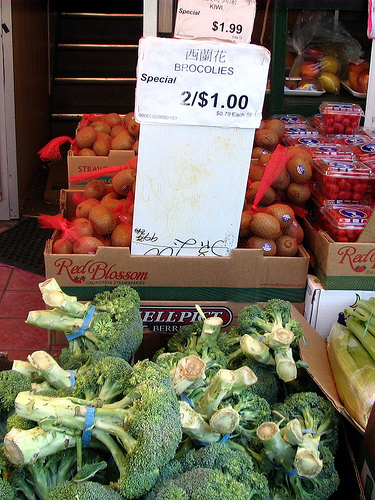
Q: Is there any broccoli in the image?
A: Yes, there is broccoli.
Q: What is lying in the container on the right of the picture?
A: The broccoli is lying in the box.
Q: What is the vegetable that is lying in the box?
A: The vegetable is broccoli.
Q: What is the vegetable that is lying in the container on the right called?
A: The vegetable is broccoli.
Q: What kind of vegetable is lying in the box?
A: The vegetable is broccoli.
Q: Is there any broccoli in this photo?
A: Yes, there is broccoli.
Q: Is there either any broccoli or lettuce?
A: Yes, there is broccoli.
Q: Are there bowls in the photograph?
A: No, there are no bowls.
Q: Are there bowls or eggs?
A: No, there are no bowls or eggs.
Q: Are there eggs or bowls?
A: No, there are no bowls or eggs.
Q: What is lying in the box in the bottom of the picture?
A: The broccoli is lying in the box.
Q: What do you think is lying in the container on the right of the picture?
A: The broccoli is lying in the box.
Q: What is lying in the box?
A: The broccoli is lying in the box.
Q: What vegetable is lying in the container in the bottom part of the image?
A: The vegetable is broccoli.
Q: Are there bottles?
A: No, there are no bottles.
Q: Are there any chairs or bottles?
A: No, there are no bottles or chairs.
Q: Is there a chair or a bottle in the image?
A: No, there are no bottles or chairs.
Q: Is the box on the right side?
A: Yes, the box is on the right of the image.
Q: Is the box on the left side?
A: No, the box is on the right of the image.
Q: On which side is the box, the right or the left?
A: The box is on the right of the image.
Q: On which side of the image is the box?
A: The box is on the right of the image.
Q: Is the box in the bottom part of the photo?
A: Yes, the box is in the bottom of the image.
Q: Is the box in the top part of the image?
A: No, the box is in the bottom of the image.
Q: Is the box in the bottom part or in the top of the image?
A: The box is in the bottom of the image.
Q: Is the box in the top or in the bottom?
A: The box is in the bottom of the image.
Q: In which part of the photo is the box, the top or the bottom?
A: The box is in the bottom of the image.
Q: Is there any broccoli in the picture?
A: Yes, there is broccoli.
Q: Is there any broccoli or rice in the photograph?
A: Yes, there is broccoli.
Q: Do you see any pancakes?
A: No, there are no pancakes.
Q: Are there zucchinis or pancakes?
A: No, there are no pancakes or zucchinis.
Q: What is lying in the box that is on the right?
A: The broccoli is lying in the box.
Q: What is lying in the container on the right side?
A: The broccoli is lying in the box.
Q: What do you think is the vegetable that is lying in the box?
A: The vegetable is broccoli.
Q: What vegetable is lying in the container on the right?
A: The vegetable is broccoli.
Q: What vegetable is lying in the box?
A: The vegetable is broccoli.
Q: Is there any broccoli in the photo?
A: Yes, there is broccoli.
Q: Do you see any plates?
A: No, there are no plates.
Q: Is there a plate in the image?
A: No, there are no plates.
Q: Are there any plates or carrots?
A: No, there are no plates or carrots.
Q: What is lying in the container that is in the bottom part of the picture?
A: The broccoli is lying in the box.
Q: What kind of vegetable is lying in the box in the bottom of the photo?
A: The vegetable is broccoli.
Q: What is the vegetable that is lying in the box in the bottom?
A: The vegetable is broccoli.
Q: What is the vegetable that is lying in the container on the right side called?
A: The vegetable is broccoli.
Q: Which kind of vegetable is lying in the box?
A: The vegetable is broccoli.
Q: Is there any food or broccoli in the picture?
A: Yes, there is broccoli.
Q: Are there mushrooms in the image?
A: No, there are no mushrooms.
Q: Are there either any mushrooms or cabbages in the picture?
A: No, there are no mushrooms or cabbages.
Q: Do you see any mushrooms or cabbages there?
A: No, there are no mushrooms or cabbages.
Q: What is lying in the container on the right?
A: The broccoli is lying in the box.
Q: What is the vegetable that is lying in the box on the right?
A: The vegetable is broccoli.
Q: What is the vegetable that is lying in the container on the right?
A: The vegetable is broccoli.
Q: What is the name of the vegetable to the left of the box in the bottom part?
A: The vegetable is broccoli.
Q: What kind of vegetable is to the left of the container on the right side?
A: The vegetable is broccoli.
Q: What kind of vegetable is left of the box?
A: The vegetable is broccoli.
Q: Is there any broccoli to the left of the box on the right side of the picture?
A: Yes, there is broccoli to the left of the box.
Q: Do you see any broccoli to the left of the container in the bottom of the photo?
A: Yes, there is broccoli to the left of the box.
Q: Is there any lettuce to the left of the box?
A: No, there is broccoli to the left of the box.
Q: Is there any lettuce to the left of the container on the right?
A: No, there is broccoli to the left of the box.